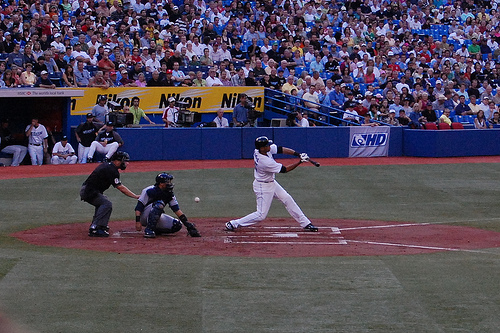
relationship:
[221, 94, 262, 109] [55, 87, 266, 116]
nikon on banner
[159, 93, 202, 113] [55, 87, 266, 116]
nikon on banner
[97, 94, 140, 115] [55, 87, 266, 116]
nikon on banner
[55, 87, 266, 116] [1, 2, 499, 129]
banner in stands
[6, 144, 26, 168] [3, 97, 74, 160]
legs in dugout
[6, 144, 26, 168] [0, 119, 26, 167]
legs belong to man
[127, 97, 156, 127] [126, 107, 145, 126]
man in shirt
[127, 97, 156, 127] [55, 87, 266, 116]
man in front of banner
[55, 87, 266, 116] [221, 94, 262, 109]
banner for nikon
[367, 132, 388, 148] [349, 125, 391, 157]
hd on banner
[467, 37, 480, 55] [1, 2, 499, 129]
man in stands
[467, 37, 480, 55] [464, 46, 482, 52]
man wears shirt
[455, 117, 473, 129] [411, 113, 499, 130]
seat in front row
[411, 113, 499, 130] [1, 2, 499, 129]
front row in stands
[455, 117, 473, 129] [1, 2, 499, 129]
seat in stands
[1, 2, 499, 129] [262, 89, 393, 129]
bleacher has rails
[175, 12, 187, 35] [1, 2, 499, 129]
person in stands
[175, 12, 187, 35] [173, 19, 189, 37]
person wears outfit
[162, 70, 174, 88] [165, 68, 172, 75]
person wears baseball cap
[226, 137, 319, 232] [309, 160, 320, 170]
baseball player with bat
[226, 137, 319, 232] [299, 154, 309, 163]
baseball player has hands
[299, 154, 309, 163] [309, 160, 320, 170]
hands hold bat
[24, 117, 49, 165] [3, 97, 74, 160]
player standing in dugout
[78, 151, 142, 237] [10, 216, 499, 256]
umpire crouched in dirt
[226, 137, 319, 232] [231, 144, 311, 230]
baseball player wears uniform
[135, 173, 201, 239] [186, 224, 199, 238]
catcher has mitt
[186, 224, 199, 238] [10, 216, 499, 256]
mitt on dirt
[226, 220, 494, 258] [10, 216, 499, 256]
lines in dirt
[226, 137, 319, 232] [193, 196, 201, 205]
baseball player missed ball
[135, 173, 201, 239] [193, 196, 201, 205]
catcher waiting for baseball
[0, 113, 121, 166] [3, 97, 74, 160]
players in dugout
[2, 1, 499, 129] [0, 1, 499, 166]
spectators in stadium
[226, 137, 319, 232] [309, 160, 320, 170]
baseball player swinging bat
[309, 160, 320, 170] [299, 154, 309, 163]
bat in hands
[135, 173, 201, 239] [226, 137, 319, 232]
catcher standing behind baseball player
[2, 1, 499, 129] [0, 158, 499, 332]
spectators at baseball game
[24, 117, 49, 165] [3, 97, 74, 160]
player stands in dugout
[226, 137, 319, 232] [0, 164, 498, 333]
baseball player in field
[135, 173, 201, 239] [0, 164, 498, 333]
catcher in field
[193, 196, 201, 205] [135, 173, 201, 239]
baseball headed for catcher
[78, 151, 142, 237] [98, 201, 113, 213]
umpire has knees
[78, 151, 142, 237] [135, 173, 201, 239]
umpire leans hand on catcher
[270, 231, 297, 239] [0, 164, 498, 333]
home plate surrounded by field